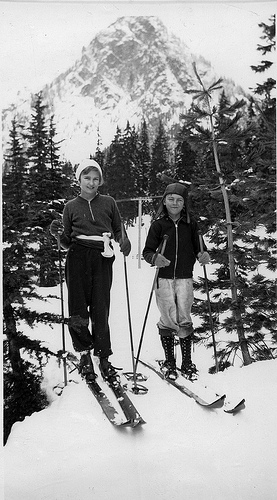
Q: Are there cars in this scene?
A: No, there are no cars.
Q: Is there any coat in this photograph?
A: Yes, there is a coat.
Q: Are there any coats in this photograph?
A: Yes, there is a coat.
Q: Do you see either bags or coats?
A: Yes, there is a coat.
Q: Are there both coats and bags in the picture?
A: No, there is a coat but no bags.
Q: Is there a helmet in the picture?
A: No, there are no helmets.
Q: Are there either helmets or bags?
A: No, there are no helmets or bags.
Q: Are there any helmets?
A: No, there are no helmets.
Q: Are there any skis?
A: Yes, there are skis.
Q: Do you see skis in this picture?
A: Yes, there are skis.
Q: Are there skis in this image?
A: Yes, there are skis.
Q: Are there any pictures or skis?
A: Yes, there are skis.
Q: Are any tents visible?
A: No, there are no tents.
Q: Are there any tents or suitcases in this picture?
A: No, there are no tents or suitcases.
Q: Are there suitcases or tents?
A: No, there are no tents or suitcases.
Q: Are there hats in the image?
A: Yes, there is a hat.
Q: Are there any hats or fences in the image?
A: Yes, there is a hat.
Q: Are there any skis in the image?
A: Yes, there are skis.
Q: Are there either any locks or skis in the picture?
A: Yes, there are skis.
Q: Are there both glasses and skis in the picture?
A: No, there are skis but no glasses.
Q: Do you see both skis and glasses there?
A: No, there are skis but no glasses.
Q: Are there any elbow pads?
A: No, there are no elbow pads.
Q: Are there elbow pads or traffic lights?
A: No, there are no elbow pads or traffic lights.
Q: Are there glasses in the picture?
A: No, there are no glasses.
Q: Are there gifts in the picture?
A: No, there are no gifts.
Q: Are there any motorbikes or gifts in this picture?
A: No, there are no gifts or motorbikes.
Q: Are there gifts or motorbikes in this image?
A: No, there are no gifts or motorbikes.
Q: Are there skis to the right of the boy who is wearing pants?
A: Yes, there is a ski to the right of the boy.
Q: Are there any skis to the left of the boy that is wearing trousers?
A: No, the ski is to the right of the boy.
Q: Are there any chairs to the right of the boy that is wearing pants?
A: No, there is a ski to the right of the boy.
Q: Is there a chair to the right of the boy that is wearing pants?
A: No, there is a ski to the right of the boy.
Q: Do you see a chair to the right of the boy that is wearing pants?
A: No, there is a ski to the right of the boy.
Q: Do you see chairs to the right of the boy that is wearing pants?
A: No, there is a ski to the right of the boy.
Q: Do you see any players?
A: No, there are no players.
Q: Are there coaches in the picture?
A: No, there are no coaches.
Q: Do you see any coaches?
A: No, there are no coaches.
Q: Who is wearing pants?
A: The boy is wearing pants.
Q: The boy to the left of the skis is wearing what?
A: The boy is wearing trousers.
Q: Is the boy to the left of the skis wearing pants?
A: Yes, the boy is wearing pants.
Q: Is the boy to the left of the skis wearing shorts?
A: No, the boy is wearing pants.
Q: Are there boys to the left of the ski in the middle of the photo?
A: Yes, there is a boy to the left of the ski.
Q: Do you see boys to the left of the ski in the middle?
A: Yes, there is a boy to the left of the ski.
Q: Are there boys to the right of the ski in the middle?
A: No, the boy is to the left of the ski.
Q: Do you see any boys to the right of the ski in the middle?
A: No, the boy is to the left of the ski.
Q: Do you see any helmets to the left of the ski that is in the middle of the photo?
A: No, there is a boy to the left of the ski.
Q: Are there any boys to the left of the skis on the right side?
A: Yes, there is a boy to the left of the skis.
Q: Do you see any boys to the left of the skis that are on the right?
A: Yes, there is a boy to the left of the skis.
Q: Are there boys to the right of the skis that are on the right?
A: No, the boy is to the left of the skis.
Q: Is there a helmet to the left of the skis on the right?
A: No, there is a boy to the left of the skis.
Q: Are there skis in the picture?
A: Yes, there are skis.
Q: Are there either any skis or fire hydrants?
A: Yes, there are skis.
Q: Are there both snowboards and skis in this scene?
A: No, there are skis but no snowboards.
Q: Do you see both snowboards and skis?
A: No, there are skis but no snowboards.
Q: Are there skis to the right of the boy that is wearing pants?
A: Yes, there are skis to the right of the boy.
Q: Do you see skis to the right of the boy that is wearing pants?
A: Yes, there are skis to the right of the boy.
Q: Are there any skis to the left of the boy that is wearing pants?
A: No, the skis are to the right of the boy.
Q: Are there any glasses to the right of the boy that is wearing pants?
A: No, there are skis to the right of the boy.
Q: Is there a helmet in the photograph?
A: No, there are no helmets.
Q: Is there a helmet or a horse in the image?
A: No, there are no helmets or horses.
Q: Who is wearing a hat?
A: The boy is wearing a hat.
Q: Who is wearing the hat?
A: The boy is wearing a hat.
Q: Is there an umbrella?
A: No, there are no umbrellas.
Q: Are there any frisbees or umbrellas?
A: No, there are no umbrellas or frisbees.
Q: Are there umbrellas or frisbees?
A: No, there are no umbrellas or frisbees.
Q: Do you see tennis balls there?
A: No, there are no tennis balls.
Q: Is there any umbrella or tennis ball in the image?
A: No, there are no tennis balls or umbrellas.